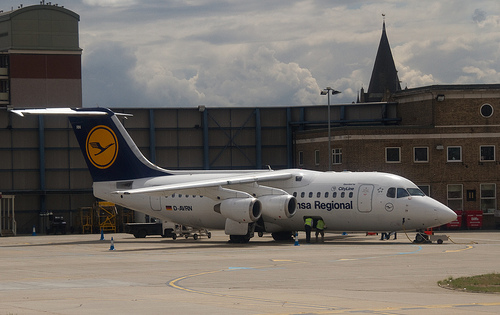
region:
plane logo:
[84, 121, 164, 186]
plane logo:
[79, 93, 145, 198]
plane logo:
[85, 105, 105, 175]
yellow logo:
[40, 120, 150, 171]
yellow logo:
[85, 106, 150, 187]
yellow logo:
[50, 125, 151, 207]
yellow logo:
[78, 128, 132, 176]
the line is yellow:
[167, 267, 185, 304]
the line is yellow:
[174, 273, 175, 285]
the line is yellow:
[169, 278, 189, 293]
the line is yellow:
[172, 274, 184, 294]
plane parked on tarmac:
[14, 100, 459, 250]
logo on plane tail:
[76, 115, 126, 180]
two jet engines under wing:
[216, 185, 305, 229]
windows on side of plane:
[288, 183, 356, 208]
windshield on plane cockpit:
[379, 177, 426, 204]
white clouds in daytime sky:
[211, 27, 316, 103]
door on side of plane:
[343, 175, 380, 222]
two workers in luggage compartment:
[292, 204, 330, 244]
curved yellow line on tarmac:
[158, 265, 219, 296]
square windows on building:
[372, 134, 484, 175]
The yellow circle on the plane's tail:
[81, 123, 121, 175]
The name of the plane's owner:
[294, 197, 359, 216]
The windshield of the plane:
[382, 182, 427, 199]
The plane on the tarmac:
[11, 96, 458, 250]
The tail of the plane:
[13, 101, 161, 181]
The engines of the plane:
[206, 183, 299, 230]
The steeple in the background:
[354, 7, 414, 99]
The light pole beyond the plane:
[318, 82, 343, 171]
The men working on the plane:
[301, 211, 326, 247]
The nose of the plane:
[396, 188, 458, 235]